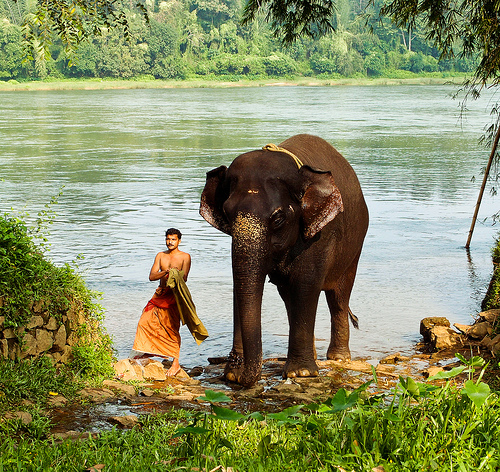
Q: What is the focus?
A: Elephant climbing out of river.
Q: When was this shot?
A: Daytime.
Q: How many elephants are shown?
A: 1.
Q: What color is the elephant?
A: Grey.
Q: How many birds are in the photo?
A: 0.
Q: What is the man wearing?
A: Skirt.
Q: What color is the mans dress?
A: Orange.